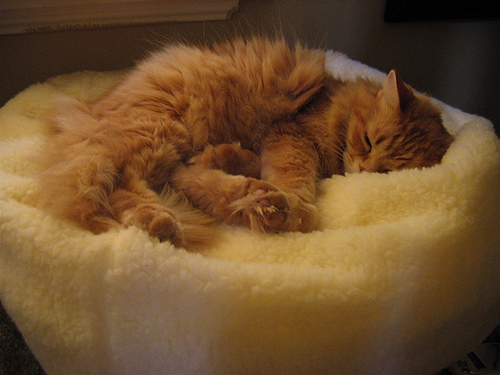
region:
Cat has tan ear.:
[366, 71, 407, 116]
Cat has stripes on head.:
[394, 107, 432, 162]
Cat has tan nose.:
[361, 158, 375, 176]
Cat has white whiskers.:
[321, 125, 353, 172]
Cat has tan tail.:
[54, 95, 96, 216]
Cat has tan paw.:
[124, 188, 207, 284]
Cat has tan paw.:
[221, 173, 303, 262]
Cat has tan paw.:
[282, 179, 302, 239]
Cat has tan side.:
[102, 46, 270, 119]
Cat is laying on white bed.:
[66, 60, 421, 329]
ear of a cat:
[382, 68, 416, 110]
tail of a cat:
[23, 78, 145, 248]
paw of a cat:
[127, 193, 184, 245]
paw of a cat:
[231, 177, 293, 231]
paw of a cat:
[190, 142, 262, 176]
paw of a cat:
[263, 189, 329, 231]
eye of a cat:
[360, 123, 374, 154]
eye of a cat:
[378, 160, 394, 177]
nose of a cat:
[355, 156, 382, 177]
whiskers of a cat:
[310, 120, 363, 169]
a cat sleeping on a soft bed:
[36, 34, 452, 251]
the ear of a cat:
[378, 64, 419, 114]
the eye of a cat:
[358, 120, 377, 154]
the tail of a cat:
[41, 104, 125, 234]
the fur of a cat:
[176, 63, 221, 106]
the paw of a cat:
[123, 200, 188, 250]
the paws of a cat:
[236, 175, 323, 242]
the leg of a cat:
[262, 136, 325, 226]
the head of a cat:
[342, 67, 451, 177]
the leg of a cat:
[180, 165, 286, 230]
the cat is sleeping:
[46, 36, 435, 228]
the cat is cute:
[68, 43, 439, 230]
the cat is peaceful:
[64, 48, 471, 243]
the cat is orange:
[68, 53, 433, 231]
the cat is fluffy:
[67, 33, 429, 250]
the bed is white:
[232, 268, 403, 345]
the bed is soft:
[59, 243, 207, 338]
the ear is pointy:
[372, 67, 409, 110]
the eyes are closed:
[354, 126, 391, 166]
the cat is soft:
[65, 49, 417, 235]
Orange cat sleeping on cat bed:
[0, 18, 490, 366]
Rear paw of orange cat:
[225, 176, 290, 233]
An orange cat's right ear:
[377, 70, 410, 113]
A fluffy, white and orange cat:
[55, 29, 452, 244]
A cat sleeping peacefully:
[70, 18, 457, 253]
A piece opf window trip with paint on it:
[0, 0, 248, 37]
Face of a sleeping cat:
[333, 68, 456, 190]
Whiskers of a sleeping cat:
[317, 120, 362, 171]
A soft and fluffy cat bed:
[13, 65, 489, 362]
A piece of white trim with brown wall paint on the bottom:
[5, 0, 258, 29]